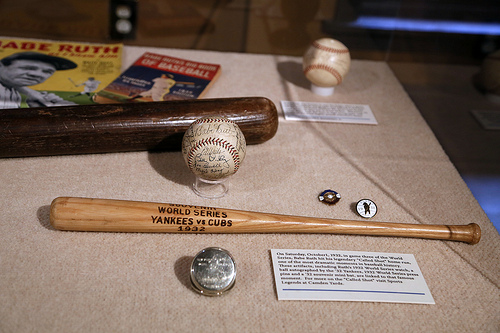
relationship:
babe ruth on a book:
[0, 50, 78, 106] [0, 37, 122, 108]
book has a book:
[0, 37, 122, 108] [0, 37, 122, 108]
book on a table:
[100, 50, 221, 117] [3, 41, 493, 324]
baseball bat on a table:
[2, 99, 278, 160] [3, 41, 493, 324]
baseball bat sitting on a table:
[47, 193, 480, 250] [3, 41, 493, 324]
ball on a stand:
[181, 116, 247, 180] [189, 171, 227, 193]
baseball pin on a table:
[317, 189, 338, 204] [3, 41, 493, 324]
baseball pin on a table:
[350, 197, 376, 218] [3, 41, 493, 324]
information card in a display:
[279, 96, 374, 126] [4, 5, 496, 330]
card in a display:
[271, 249, 436, 305] [4, 5, 496, 330]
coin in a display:
[189, 247, 237, 297] [4, 5, 496, 330]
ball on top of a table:
[181, 116, 247, 180] [3, 41, 493, 324]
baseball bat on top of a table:
[49, 196, 481, 246] [3, 41, 493, 324]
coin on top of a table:
[189, 243, 235, 293] [3, 41, 493, 324]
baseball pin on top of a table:
[355, 198, 377, 217] [3, 41, 493, 324]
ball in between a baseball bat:
[181, 116, 247, 180] [0, 96, 278, 159]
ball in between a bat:
[181, 116, 247, 180] [50, 196, 480, 246]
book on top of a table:
[2, 37, 124, 112] [3, 41, 493, 324]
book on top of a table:
[100, 50, 221, 117] [3, 41, 493, 324]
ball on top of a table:
[303, 38, 351, 87] [3, 41, 493, 324]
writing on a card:
[278, 253, 418, 291] [267, 249, 436, 306]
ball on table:
[181, 116, 247, 180] [82, 160, 145, 190]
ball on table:
[303, 38, 351, 87] [109, 279, 132, 299]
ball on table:
[181, 116, 247, 180] [77, 233, 127, 263]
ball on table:
[303, 38, 351, 87] [108, 266, 144, 300]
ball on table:
[181, 116, 247, 180] [73, 256, 155, 296]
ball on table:
[303, 38, 351, 87] [92, 266, 134, 294]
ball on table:
[181, 116, 247, 180] [76, 279, 113, 311]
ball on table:
[303, 38, 351, 87] [58, 239, 105, 280]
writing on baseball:
[184, 144, 223, 180] [181, 119, 242, 171]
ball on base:
[298, 32, 349, 82] [310, 79, 336, 99]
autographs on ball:
[199, 143, 223, 164] [166, 109, 256, 185]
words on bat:
[147, 202, 255, 245] [34, 173, 496, 269]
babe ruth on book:
[0, 51, 78, 108] [0, 37, 122, 108]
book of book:
[0, 37, 122, 108] [0, 28, 119, 98]